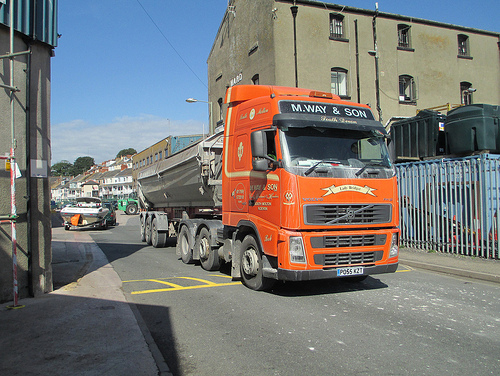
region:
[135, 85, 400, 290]
the large truck on the street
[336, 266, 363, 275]
the license plate on the truck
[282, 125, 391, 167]
the windshield on the truck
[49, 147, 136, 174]
the trees in the distance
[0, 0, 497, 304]
the buildings around the street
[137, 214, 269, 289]
the wheels on the truck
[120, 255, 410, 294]
the yellow lines on the speedbump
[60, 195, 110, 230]
the boat being towed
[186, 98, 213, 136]
the street light near the building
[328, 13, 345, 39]
the window on the building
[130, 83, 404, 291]
Tanker truck with red cab.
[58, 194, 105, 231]
Motor boat on towing trailer.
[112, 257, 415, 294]
Yellow painted crosswalk on narrow city street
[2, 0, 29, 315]
Construction scaffolding on side of building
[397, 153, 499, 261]
Metal, parking lot security fence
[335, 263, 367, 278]
License plate on front of tanker trailer truck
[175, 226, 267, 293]
Heavy-duty tires and wheels on tanker trailer truck.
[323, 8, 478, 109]
Glass windows on stark side of three story cement building.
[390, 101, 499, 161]
Buses parked in security lot.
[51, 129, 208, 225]
Row of buildings facing a narrow city street.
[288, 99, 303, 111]
The letter is white.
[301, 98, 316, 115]
The letter is white.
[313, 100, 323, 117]
The letter is white.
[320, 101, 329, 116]
The letter is white.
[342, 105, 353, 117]
The letter is white.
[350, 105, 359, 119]
The letter is white.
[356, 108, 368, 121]
The letter is white.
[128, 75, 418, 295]
The cab of the truck is orange.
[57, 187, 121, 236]
The car is towing a boat.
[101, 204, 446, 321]
The street has yellow lines painted on it.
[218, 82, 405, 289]
Truck is painted orange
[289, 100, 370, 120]
Sign on truck says M.Way and Son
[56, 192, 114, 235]
Boat being towed on the street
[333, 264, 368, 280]
License plate on the truck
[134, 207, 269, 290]
Six wheels on the truck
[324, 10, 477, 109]
Six windows on the building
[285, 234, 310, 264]
Headlight on the truck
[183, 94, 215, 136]
Street light near the building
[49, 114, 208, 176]
Clouds in the blue sky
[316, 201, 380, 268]
Truck has three air vents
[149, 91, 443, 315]
Orange truck on street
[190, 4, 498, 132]
Brown building in background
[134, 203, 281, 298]
Six tires on the truck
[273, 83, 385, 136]
M.Way & Son written on truck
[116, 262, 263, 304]
Yellow lines in street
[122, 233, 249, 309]
Yellow lines below truck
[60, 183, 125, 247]
Boat in the distance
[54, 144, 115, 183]
Trees in the distance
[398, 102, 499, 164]
Big black bins on the side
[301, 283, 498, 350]
White spots in the street